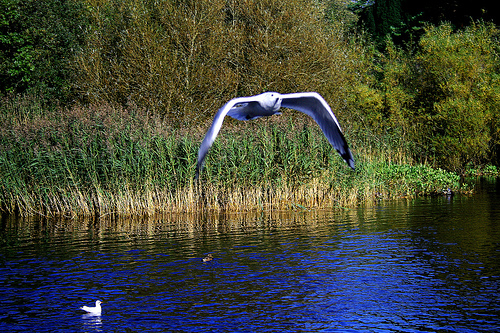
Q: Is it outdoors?
A: Yes, it is outdoors.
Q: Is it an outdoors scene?
A: Yes, it is outdoors.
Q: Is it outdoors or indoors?
A: It is outdoors.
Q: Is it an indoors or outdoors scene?
A: It is outdoors.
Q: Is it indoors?
A: No, it is outdoors.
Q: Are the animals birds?
A: Yes, all the animals are birds.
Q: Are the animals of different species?
A: No, all the animals are birds.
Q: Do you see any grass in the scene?
A: Yes, there is grass.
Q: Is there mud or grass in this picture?
A: Yes, there is grass.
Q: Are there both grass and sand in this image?
A: No, there is grass but no sand.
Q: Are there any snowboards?
A: No, there are no snowboards.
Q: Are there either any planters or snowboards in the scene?
A: No, there are no snowboards or planters.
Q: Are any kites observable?
A: No, there are no kites.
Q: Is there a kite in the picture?
A: No, there are no kites.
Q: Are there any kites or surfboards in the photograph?
A: No, there are no kites or surfboards.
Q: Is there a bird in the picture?
A: Yes, there is a bird.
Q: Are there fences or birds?
A: Yes, there is a bird.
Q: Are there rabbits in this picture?
A: No, there are no rabbits.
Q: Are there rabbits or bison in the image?
A: No, there are no rabbits or bison.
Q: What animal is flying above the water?
A: The bird is flying above the water.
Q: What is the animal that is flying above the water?
A: The animal is a bird.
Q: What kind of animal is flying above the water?
A: The animal is a bird.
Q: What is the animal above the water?
A: The animal is a bird.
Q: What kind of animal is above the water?
A: The animal is a bird.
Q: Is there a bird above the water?
A: Yes, there is a bird above the water.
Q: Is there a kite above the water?
A: No, there is a bird above the water.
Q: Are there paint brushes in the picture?
A: No, there are no paint brushes.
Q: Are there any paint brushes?
A: No, there are no paint brushes.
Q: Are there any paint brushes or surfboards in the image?
A: No, there are no paint brushes or surfboards.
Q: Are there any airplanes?
A: No, there are no airplanes.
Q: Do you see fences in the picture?
A: No, there are no fences.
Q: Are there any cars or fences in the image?
A: No, there are no fences or cars.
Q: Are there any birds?
A: Yes, there is a bird.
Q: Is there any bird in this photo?
A: Yes, there is a bird.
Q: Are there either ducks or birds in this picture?
A: Yes, there is a bird.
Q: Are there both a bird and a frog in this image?
A: No, there is a bird but no frogs.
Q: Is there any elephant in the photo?
A: No, there are no elephants.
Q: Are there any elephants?
A: No, there are no elephants.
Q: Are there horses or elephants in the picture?
A: No, there are no elephants or horses.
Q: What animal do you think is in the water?
A: The bird is in the water.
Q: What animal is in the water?
A: The bird is in the water.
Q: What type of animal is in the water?
A: The animal is a bird.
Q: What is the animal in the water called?
A: The animal is a bird.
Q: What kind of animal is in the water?
A: The animal is a bird.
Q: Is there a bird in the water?
A: Yes, there is a bird in the water.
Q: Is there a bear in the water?
A: No, there is a bird in the water.